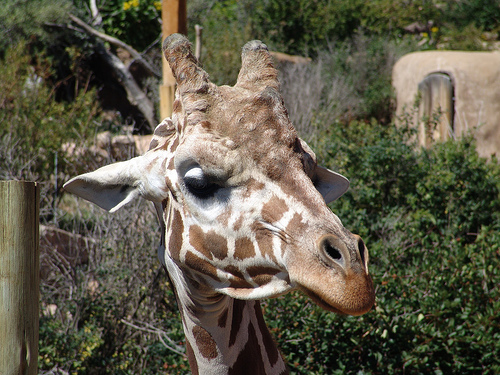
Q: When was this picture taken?
A: Daytime.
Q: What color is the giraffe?
A: Brown and white.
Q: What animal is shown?
A: A giraffe.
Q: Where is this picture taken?
A: A zoo.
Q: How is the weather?
A: Sunny.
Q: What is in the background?
A: Trees.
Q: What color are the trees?
A: Green.